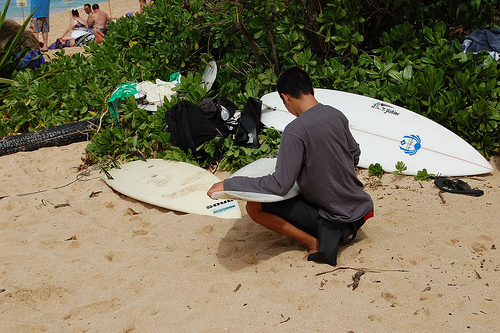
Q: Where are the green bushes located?
A: On the beach.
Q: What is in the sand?
A: The white surfboard.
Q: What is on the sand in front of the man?
A: The board.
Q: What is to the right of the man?
A: The board.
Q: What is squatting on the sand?
A: The man.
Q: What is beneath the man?
A: The sand.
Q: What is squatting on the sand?
A: A young man.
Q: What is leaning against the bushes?
A: The white surfboard.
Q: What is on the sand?
A: The white surfboard.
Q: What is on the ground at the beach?
A: The sand.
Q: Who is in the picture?
A: A man.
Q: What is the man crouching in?
A: Sand.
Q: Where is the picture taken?
A: Beach.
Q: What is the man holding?
A: A surfboard.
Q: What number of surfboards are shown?
A: Three.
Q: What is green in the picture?
A: Shrubs.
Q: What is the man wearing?
A: A gray tee shirt.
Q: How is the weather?
A: Sunny.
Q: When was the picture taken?
A: Afternoon.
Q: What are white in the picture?
A: Surfboards.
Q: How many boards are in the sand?
A: 2.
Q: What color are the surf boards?
A: White.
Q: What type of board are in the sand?
A: Surf boards.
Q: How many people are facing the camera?
A: 0.